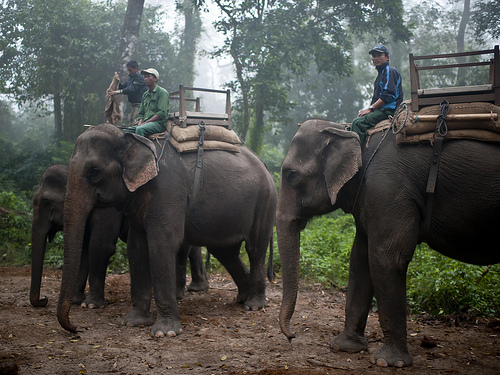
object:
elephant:
[51, 122, 278, 317]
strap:
[187, 128, 211, 205]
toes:
[145, 310, 186, 341]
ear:
[120, 132, 160, 193]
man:
[110, 60, 144, 129]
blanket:
[103, 69, 123, 124]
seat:
[168, 83, 233, 131]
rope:
[156, 125, 175, 164]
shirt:
[132, 85, 170, 123]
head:
[123, 56, 143, 74]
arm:
[108, 83, 137, 97]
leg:
[144, 211, 186, 338]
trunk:
[52, 194, 97, 339]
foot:
[145, 301, 189, 340]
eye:
[84, 166, 105, 184]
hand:
[104, 89, 115, 98]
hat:
[139, 67, 159, 79]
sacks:
[166, 123, 242, 144]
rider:
[120, 65, 172, 137]